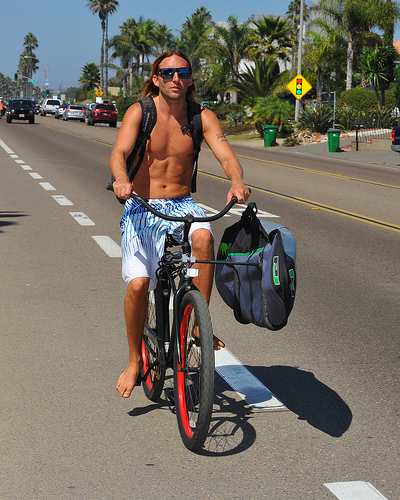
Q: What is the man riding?
A: Bike.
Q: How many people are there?
A: 1.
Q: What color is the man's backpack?
A: Black.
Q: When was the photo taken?
A: Afternoon.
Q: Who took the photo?
A: Bystander.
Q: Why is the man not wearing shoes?
A: Beach.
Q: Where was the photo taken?
A: Street.